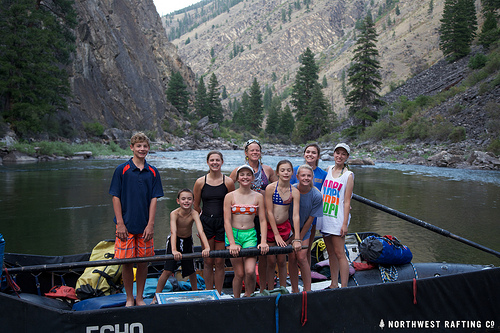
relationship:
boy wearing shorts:
[107, 134, 164, 295] [105, 231, 162, 268]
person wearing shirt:
[192, 150, 234, 294] [199, 173, 230, 230]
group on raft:
[107, 132, 354, 307] [51, 255, 230, 313]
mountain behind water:
[0, 0, 178, 144] [18, 166, 73, 222]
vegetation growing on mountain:
[0, 0, 77, 145] [1, 0, 221, 153]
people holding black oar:
[106, 131, 356, 309] [137, 240, 314, 263]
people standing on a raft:
[106, 129, 356, 305] [1, 245, 499, 331]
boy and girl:
[150, 190, 209, 303] [264, 161, 299, 293]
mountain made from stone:
[6, 3, 178, 127] [127, 30, 165, 75]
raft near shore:
[1, 245, 499, 331] [261, 143, 498, 170]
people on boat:
[106, 131, 356, 309] [87, 257, 450, 329]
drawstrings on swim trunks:
[179, 238, 182, 253] [162, 235, 194, 273]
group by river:
[107, 132, 354, 307] [0, 149, 498, 263]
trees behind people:
[165, 47, 343, 139] [109, 119, 366, 309]